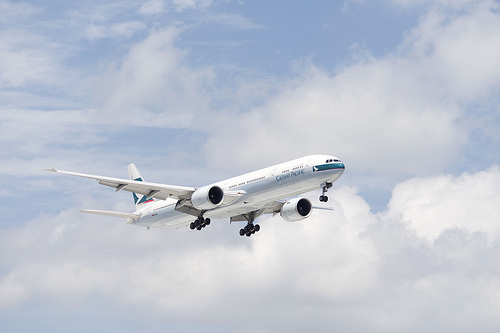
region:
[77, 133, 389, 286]
airplane flying in a sky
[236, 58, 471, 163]
lots of clouds in the sky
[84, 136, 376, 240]
airplane is white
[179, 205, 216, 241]
airplane has black tires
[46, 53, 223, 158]
the sky is very cloudy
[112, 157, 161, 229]
plane has a blue tail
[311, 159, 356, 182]
plane has a blue front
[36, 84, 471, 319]
airplane is very big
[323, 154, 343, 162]
airplane has front windows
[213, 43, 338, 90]
the sky is very cloudy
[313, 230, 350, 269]
part of a cloud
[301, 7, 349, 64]
part of the sky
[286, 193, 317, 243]
part of an engine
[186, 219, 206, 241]
part of a wheel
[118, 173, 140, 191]
edge of a wing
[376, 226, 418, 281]
edge of a cloud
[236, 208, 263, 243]
part of a wheel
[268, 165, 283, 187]
part of a graphic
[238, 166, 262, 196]
part of some windows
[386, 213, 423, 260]
part of a cloud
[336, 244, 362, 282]
the sky is cloudy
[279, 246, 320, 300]
the sky is cloudy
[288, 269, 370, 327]
the sky is cloudy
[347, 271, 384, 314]
the sky is cloudy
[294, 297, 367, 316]
the sky is cloudy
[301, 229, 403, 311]
the sky is cloudy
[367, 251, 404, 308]
the sky is cloudy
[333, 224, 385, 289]
the sky is cloudy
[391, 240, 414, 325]
the sky is cloudy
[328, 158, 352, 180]
The nose of the plane.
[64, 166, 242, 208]
The left side wing of the plane.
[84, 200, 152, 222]
The small side wing near the tail of the plane.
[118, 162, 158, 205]
The tail of the plane.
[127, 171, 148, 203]
The blue design on the tail of the plane.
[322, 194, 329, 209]
The small front wheels of the plane.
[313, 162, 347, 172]
The blue stripe on the front of the plane.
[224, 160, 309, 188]
The small passenger windows on the plane.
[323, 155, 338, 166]
The windows of the cockpit.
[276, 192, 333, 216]
The right side wing of the plane.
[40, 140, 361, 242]
airplane flying in the sky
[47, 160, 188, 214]
wing on the airplane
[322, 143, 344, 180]
windows on the airplane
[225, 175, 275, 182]
windows on the plane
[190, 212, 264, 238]
landing gear on the plane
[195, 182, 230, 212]
engine on the plane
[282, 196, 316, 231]
engine on the plane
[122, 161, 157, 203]
tail on the plane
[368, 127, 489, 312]
clouds in the sky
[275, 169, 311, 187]
writing on the plane